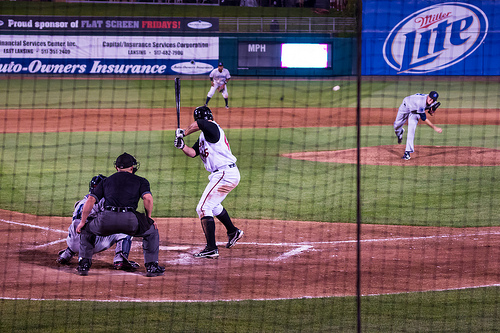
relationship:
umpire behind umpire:
[78, 151, 163, 287] [73, 151, 167, 277]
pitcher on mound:
[390, 92, 443, 159] [288, 142, 495, 165]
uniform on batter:
[186, 116, 246, 213] [169, 92, 250, 261]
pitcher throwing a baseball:
[391, 89, 444, 162] [331, 84, 342, 93]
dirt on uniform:
[219, 181, 228, 193] [164, 121, 298, 233]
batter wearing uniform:
[172, 104, 244, 261] [183, 121, 247, 221]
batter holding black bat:
[171, 79, 247, 257] [170, 72, 182, 143]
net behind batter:
[268, 83, 405, 279] [174, 97, 252, 267]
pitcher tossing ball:
[391, 89, 444, 162] [330, 79, 342, 98]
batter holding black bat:
[172, 104, 244, 261] [172, 76, 184, 149]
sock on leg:
[190, 214, 222, 257] [196, 175, 228, 257]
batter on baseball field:
[172, 104, 244, 261] [0, 74, 499, 331]